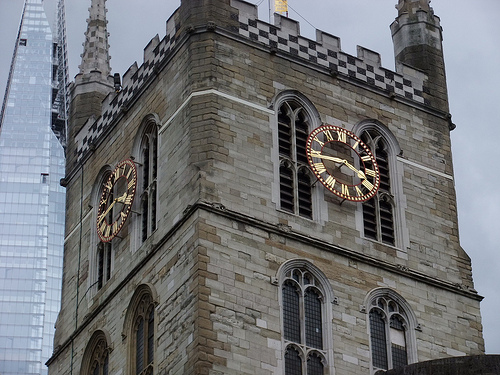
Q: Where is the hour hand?
A: On three.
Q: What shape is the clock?
A: Round.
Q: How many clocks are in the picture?
A: Two.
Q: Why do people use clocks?
A: Tell time.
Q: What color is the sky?
A: Gray.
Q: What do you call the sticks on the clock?
A: Hands.